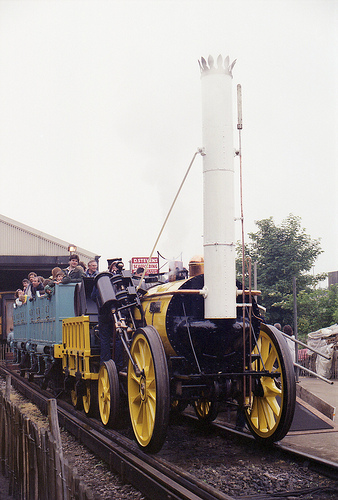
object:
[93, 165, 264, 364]
engine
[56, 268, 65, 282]
passengers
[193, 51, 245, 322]
stack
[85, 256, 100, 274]
people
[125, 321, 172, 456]
wheel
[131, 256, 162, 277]
signage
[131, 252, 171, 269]
arrow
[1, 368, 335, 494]
tracks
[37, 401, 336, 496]
gravel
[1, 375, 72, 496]
fence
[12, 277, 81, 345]
bucket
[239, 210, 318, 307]
tree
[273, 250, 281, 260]
leaves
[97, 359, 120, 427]
wheel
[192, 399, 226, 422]
wheel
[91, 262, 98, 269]
face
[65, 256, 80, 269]
face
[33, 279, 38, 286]
face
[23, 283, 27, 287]
face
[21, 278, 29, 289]
person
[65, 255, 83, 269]
person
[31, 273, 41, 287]
person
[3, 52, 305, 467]
car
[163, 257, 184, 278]
whistle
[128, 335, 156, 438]
interior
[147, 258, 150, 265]
something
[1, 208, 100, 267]
roof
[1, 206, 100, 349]
station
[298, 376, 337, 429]
ramp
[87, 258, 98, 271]
head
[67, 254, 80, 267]
head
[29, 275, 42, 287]
head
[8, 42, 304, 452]
train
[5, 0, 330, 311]
open air